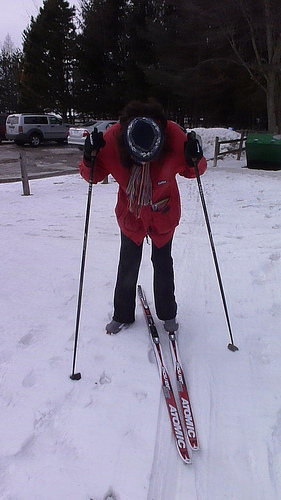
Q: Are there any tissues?
A: No, there are no tissues.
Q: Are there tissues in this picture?
A: No, there are no tissues.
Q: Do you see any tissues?
A: No, there are no tissues.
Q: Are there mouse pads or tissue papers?
A: No, there are no tissue papers or mouse pads.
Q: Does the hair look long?
A: Yes, the hair is long.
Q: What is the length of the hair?
A: The hair is long.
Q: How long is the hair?
A: The hair is long.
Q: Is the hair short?
A: No, the hair is long.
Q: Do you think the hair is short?
A: No, the hair is long.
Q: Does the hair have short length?
A: No, the hair is long.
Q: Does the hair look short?
A: No, the hair is long.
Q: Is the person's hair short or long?
A: The hair is long.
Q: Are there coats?
A: Yes, there is a coat.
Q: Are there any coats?
A: Yes, there is a coat.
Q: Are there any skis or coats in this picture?
A: Yes, there is a coat.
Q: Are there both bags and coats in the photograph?
A: No, there is a coat but no bags.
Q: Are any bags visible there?
A: No, there are no bags.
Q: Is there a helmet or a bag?
A: No, there are no bags or helmets.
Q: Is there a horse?
A: No, there are no horses.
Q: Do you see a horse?
A: No, there are no horses.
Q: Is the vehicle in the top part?
A: Yes, the vehicle is in the top of the image.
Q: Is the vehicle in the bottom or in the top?
A: The vehicle is in the top of the image.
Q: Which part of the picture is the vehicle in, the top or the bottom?
A: The vehicle is in the top of the image.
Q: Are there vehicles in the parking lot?
A: Yes, there is a vehicle in the parking lot.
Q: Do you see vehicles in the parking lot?
A: Yes, there is a vehicle in the parking lot.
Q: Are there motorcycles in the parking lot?
A: No, there is a vehicle in the parking lot.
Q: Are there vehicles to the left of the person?
A: Yes, there is a vehicle to the left of the person.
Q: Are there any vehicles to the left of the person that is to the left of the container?
A: Yes, there is a vehicle to the left of the person.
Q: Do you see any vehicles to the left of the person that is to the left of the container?
A: Yes, there is a vehicle to the left of the person.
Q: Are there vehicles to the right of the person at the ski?
A: No, the vehicle is to the left of the person.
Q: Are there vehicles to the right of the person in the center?
A: No, the vehicle is to the left of the person.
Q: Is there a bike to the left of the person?
A: No, there is a vehicle to the left of the person.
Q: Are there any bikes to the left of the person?
A: No, there is a vehicle to the left of the person.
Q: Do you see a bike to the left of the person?
A: No, there is a vehicle to the left of the person.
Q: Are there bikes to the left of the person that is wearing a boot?
A: No, there is a vehicle to the left of the person.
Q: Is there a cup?
A: No, there are no cups.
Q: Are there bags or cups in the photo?
A: No, there are no cups or bags.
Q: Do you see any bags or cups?
A: No, there are no cups or bags.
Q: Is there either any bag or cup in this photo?
A: No, there are no cups or bags.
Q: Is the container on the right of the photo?
A: Yes, the container is on the right of the image.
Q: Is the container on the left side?
A: No, the container is on the right of the image.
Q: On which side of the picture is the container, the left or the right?
A: The container is on the right of the image.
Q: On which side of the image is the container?
A: The container is on the right of the image.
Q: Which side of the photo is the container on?
A: The container is on the right of the image.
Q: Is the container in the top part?
A: Yes, the container is in the top of the image.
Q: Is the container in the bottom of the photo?
A: No, the container is in the top of the image.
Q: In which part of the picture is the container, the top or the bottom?
A: The container is in the top of the image.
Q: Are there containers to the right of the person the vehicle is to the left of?
A: Yes, there is a container to the right of the person.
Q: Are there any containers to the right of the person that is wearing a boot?
A: Yes, there is a container to the right of the person.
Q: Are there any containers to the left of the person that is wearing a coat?
A: No, the container is to the right of the person.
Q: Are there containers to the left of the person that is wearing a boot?
A: No, the container is to the right of the person.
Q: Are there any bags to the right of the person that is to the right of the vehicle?
A: No, there is a container to the right of the person.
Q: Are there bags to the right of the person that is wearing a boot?
A: No, there is a container to the right of the person.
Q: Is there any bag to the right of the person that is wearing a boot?
A: No, there is a container to the right of the person.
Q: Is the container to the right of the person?
A: Yes, the container is to the right of the person.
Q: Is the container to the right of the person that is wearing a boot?
A: Yes, the container is to the right of the person.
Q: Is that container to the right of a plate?
A: No, the container is to the right of the person.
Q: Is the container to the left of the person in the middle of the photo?
A: No, the container is to the right of the person.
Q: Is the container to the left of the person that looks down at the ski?
A: No, the container is to the right of the person.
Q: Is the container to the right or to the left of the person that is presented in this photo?
A: The container is to the right of the person.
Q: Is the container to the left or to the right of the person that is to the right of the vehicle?
A: The container is to the right of the person.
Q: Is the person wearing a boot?
A: Yes, the person is wearing a boot.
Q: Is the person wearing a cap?
A: No, the person is wearing a boot.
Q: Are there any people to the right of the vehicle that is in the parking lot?
A: Yes, there is a person to the right of the vehicle.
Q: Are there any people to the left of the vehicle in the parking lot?
A: No, the person is to the right of the vehicle.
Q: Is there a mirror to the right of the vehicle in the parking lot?
A: No, there is a person to the right of the vehicle.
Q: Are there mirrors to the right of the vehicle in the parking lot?
A: No, there is a person to the right of the vehicle.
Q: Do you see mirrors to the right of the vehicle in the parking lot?
A: No, there is a person to the right of the vehicle.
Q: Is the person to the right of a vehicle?
A: Yes, the person is to the right of a vehicle.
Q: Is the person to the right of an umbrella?
A: No, the person is to the right of a vehicle.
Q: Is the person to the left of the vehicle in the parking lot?
A: No, the person is to the right of the vehicle.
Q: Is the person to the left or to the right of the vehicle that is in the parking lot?
A: The person is to the right of the vehicle.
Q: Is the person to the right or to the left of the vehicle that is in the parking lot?
A: The person is to the right of the vehicle.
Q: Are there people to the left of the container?
A: Yes, there is a person to the left of the container.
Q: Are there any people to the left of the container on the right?
A: Yes, there is a person to the left of the container.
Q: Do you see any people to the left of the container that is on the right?
A: Yes, there is a person to the left of the container.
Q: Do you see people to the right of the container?
A: No, the person is to the left of the container.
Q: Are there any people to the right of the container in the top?
A: No, the person is to the left of the container.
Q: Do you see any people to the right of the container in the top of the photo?
A: No, the person is to the left of the container.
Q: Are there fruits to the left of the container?
A: No, there is a person to the left of the container.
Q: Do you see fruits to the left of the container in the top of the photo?
A: No, there is a person to the left of the container.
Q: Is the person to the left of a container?
A: Yes, the person is to the left of a container.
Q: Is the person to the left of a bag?
A: No, the person is to the left of a container.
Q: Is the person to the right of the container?
A: No, the person is to the left of the container.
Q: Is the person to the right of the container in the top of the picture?
A: No, the person is to the left of the container.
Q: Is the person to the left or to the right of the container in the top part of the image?
A: The person is to the left of the container.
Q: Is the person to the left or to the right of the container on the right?
A: The person is to the left of the container.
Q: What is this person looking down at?
A: The person is looking down at the ski.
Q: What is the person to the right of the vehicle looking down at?
A: The person is looking down at the ski.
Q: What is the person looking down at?
A: The person is looking down at the ski.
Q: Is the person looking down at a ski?
A: Yes, the person is looking down at a ski.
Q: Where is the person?
A: The person is at the ski.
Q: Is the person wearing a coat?
A: Yes, the person is wearing a coat.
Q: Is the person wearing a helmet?
A: No, the person is wearing a coat.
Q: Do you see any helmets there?
A: No, there are no helmets.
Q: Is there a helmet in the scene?
A: No, there are no helmets.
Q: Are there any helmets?
A: No, there are no helmets.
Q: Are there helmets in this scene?
A: No, there are no helmets.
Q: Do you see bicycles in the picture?
A: No, there are no bicycles.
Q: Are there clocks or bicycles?
A: No, there are no bicycles or clocks.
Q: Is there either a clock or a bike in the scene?
A: No, there are no bikes or clocks.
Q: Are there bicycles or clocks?
A: No, there are no bicycles or clocks.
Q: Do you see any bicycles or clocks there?
A: No, there are no bicycles or clocks.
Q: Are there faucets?
A: No, there are no faucets.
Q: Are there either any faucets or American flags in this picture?
A: No, there are no faucets or American flags.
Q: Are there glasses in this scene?
A: No, there are no glasses.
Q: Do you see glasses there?
A: No, there are no glasses.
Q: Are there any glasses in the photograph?
A: No, there are no glasses.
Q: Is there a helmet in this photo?
A: No, there are no helmets.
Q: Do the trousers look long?
A: Yes, the trousers are long.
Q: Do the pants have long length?
A: Yes, the pants are long.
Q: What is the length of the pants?
A: The pants are long.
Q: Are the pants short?
A: No, the pants are long.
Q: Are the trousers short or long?
A: The trousers are long.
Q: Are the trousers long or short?
A: The trousers are long.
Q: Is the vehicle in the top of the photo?
A: Yes, the vehicle is in the top of the image.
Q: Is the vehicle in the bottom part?
A: No, the vehicle is in the top of the image.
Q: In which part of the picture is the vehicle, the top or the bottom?
A: The vehicle is in the top of the image.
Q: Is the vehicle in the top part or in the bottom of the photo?
A: The vehicle is in the top of the image.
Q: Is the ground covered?
A: Yes, the ground is covered.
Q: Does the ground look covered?
A: Yes, the ground is covered.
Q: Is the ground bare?
A: No, the ground is covered.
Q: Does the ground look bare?
A: No, the ground is covered.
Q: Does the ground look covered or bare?
A: The ground is covered.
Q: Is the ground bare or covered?
A: The ground is covered.